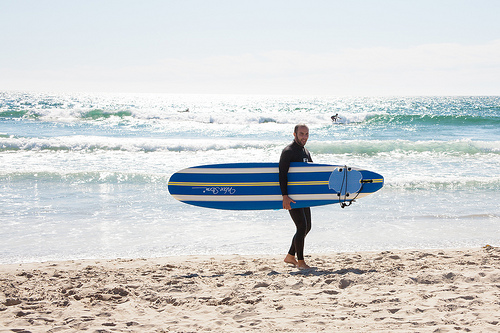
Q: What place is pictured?
A: It is an ocean.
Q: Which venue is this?
A: This is an ocean.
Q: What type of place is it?
A: It is an ocean.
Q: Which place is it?
A: It is an ocean.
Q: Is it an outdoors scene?
A: Yes, it is outdoors.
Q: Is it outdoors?
A: Yes, it is outdoors.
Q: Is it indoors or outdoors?
A: It is outdoors.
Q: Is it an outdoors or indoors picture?
A: It is outdoors.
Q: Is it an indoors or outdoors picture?
A: It is outdoors.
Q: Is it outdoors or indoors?
A: It is outdoors.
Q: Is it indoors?
A: No, it is outdoors.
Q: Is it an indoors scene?
A: No, it is outdoors.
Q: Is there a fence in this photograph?
A: No, there are no fences.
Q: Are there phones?
A: Yes, there is a phone.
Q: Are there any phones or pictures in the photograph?
A: Yes, there is a phone.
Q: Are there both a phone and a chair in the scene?
A: No, there is a phone but no chairs.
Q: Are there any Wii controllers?
A: No, there are no Wii controllers.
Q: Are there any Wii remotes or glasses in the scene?
A: No, there are no Wii remotes or glasses.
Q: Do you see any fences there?
A: No, there are no fences.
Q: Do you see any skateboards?
A: No, there are no skateboards.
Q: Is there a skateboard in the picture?
A: No, there are no skateboards.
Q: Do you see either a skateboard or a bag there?
A: No, there are no skateboards or bags.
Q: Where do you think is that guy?
A: The guy is in the sand.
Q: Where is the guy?
A: The guy is in the sand.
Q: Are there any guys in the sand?
A: Yes, there is a guy in the sand.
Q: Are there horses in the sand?
A: No, there is a guy in the sand.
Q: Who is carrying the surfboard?
A: The guy is carrying the surfboard.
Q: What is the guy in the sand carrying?
A: The guy is carrying a surf board.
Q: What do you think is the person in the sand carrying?
A: The guy is carrying a surf board.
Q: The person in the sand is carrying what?
A: The guy is carrying a surf board.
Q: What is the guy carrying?
A: The guy is carrying a surf board.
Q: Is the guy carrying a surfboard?
A: Yes, the guy is carrying a surfboard.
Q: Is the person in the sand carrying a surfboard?
A: Yes, the guy is carrying a surfboard.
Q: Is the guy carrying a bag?
A: No, the guy is carrying a surfboard.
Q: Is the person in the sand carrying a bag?
A: No, the guy is carrying a surfboard.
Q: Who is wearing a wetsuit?
A: The guy is wearing a wetsuit.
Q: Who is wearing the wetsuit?
A: The guy is wearing a wetsuit.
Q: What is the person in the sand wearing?
A: The guy is wearing a wetsuit.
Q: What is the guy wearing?
A: The guy is wearing a wetsuit.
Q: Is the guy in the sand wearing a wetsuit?
A: Yes, the guy is wearing a wetsuit.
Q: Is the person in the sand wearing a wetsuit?
A: Yes, the guy is wearing a wetsuit.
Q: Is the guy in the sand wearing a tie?
A: No, the guy is wearing a wetsuit.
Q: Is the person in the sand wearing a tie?
A: No, the guy is wearing a wetsuit.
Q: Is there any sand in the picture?
A: Yes, there is sand.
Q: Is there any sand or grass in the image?
A: Yes, there is sand.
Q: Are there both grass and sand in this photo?
A: No, there is sand but no grass.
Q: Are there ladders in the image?
A: No, there are no ladders.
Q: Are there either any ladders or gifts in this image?
A: No, there are no ladders or gifts.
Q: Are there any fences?
A: No, there are no fences.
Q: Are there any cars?
A: No, there are no cars.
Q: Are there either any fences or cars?
A: No, there are no cars or fences.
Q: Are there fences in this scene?
A: No, there are no fences.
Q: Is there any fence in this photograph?
A: No, there are no fences.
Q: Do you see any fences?
A: No, there are no fences.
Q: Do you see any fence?
A: No, there are no fences.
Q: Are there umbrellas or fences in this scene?
A: No, there are no fences or umbrellas.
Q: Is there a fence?
A: No, there are no fences.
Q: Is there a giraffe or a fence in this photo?
A: No, there are no fences or giraffes.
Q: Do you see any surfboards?
A: Yes, there is a surfboard.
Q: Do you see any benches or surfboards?
A: Yes, there is a surfboard.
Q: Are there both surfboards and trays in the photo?
A: No, there is a surfboard but no trays.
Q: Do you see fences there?
A: No, there are no fences.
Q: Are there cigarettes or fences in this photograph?
A: No, there are no fences or cigarettes.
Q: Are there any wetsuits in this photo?
A: Yes, there is a wetsuit.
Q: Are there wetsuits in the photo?
A: Yes, there is a wetsuit.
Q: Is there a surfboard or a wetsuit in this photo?
A: Yes, there is a wetsuit.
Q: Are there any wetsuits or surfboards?
A: Yes, there is a wetsuit.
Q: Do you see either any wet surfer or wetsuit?
A: Yes, there is a wet wetsuit.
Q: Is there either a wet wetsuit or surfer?
A: Yes, there is a wet wetsuit.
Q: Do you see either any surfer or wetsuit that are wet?
A: Yes, the wetsuit is wet.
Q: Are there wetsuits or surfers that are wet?
A: Yes, the wetsuit is wet.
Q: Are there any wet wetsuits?
A: Yes, there is a wet wetsuit.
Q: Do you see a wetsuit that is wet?
A: Yes, there is a wetsuit that is wet.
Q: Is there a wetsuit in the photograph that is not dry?
A: Yes, there is a wet wetsuit.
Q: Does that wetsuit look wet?
A: Yes, the wetsuit is wet.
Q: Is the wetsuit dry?
A: No, the wetsuit is wet.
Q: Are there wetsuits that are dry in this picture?
A: No, there is a wetsuit but it is wet.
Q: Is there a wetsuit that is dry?
A: No, there is a wetsuit but it is wet.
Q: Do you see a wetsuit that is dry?
A: No, there is a wetsuit but it is wet.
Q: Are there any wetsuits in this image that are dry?
A: No, there is a wetsuit but it is wet.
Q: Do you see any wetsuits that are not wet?
A: No, there is a wetsuit but it is wet.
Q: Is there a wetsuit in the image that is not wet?
A: No, there is a wetsuit but it is wet.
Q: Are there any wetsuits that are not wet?
A: No, there is a wetsuit but it is wet.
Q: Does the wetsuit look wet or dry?
A: The wetsuit is wet.